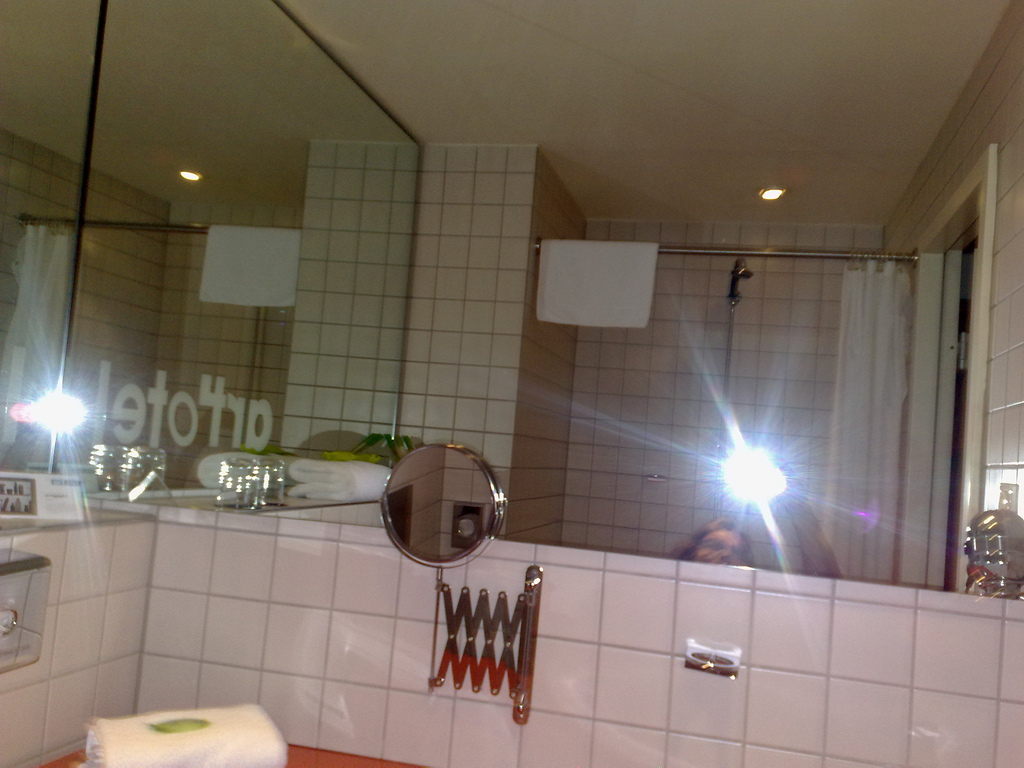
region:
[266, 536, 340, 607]
white tile on bathroom back splash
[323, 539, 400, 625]
white tile on bathroom back splash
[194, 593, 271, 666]
white tile on bathroom back splash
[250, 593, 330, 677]
white tile on bathroom back splash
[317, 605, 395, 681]
white tile on bathroom back splash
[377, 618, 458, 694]
white tile on bathroom back splash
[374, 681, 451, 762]
white tile on bathroom back splash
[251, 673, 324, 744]
white tile on bathroom back splash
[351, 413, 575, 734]
retractable mirror in bathroom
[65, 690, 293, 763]
tissue box on a counter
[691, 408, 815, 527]
flash light in the mirror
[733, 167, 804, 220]
illuminated light above a shower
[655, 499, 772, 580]
head of a woman taking a picture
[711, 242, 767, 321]
head of a shower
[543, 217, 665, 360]
towel hanging on shower curtain rod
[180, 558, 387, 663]
white tall on bathroom wall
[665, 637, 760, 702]
silver soap dish on tile wall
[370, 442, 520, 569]
a small circle mirror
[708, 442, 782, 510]
flash from the camera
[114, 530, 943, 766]
the wall is white and clean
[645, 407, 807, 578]
a person taking a picture in the mirror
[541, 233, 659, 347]
a white towel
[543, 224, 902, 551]
a shower area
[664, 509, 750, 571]
person is white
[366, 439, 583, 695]
a small mirror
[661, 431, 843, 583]
The reflection of the person taking the photo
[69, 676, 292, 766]
The towels on the sink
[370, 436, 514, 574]
The circular mirror on the metal holder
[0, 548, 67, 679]
The silver tissue box on the wall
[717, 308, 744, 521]
The water line leading up to the shower head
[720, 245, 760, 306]
The shower head at the end of the water line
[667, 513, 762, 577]
The head of the woman taking the photo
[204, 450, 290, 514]
The two glasses on the shelf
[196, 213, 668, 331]
The towels hanging from the curtain rod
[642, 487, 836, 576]
reflection of a woman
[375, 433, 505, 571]
small circular mirror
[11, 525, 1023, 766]
pink tiles on the wall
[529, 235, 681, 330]
towel hanging over the shower curtain rod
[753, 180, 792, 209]
small circle on the ceiling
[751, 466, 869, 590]
arm is raised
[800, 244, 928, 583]
shower curtains are pushed to the side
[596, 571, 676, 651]
A tile on the wall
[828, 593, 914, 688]
A tile on the wall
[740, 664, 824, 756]
A tile on the wall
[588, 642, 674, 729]
A tile on the wall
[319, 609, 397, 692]
A tile on the wall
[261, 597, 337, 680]
A tile on the wall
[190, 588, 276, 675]
A tile on the wall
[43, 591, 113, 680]
A tile on the wall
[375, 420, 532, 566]
small circular mirror in bathroom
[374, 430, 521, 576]
small circular mirror in bathroom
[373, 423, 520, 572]
small circular mirror in bathroom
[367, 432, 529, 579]
small circular mirror in bathroom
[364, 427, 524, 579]
small circular mirror in bathroom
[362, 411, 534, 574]
small circular mirror in bathroom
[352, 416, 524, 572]
small circular mirror in bathroom